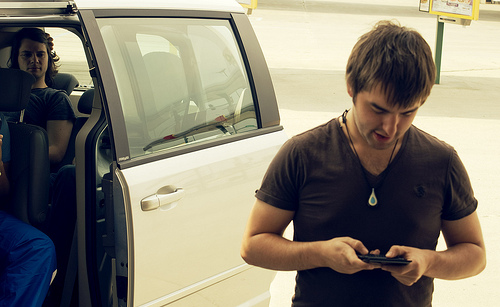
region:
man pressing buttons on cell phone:
[240, 10, 490, 304]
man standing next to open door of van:
[239, 17, 490, 303]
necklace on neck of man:
[334, 98, 411, 213]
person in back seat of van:
[2, 25, 74, 182]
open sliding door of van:
[64, 0, 288, 305]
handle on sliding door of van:
[133, 181, 198, 213]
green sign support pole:
[428, 16, 454, 87]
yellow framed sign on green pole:
[416, 0, 486, 87]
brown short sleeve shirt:
[252, 116, 480, 306]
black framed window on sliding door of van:
[81, 5, 286, 170]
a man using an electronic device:
[240, 18, 485, 305]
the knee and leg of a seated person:
[1, 208, 62, 305]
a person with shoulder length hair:
[5, 27, 78, 180]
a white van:
[0, 1, 282, 304]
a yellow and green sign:
[420, 0, 477, 87]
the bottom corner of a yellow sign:
[238, 1, 258, 13]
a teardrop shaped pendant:
[365, 185, 378, 205]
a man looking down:
[238, 18, 488, 303]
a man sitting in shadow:
[3, 23, 75, 181]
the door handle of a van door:
[140, 178, 185, 215]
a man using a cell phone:
[318, 30, 445, 282]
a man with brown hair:
[326, 13, 453, 103]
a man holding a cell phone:
[333, 238, 430, 282]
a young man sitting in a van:
[2, 18, 69, 149]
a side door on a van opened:
[6, 8, 265, 305]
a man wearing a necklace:
[349, 47, 438, 216]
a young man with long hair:
[12, 25, 64, 86]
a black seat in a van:
[6, 72, 50, 227]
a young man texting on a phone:
[314, 198, 439, 293]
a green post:
[423, 9, 457, 85]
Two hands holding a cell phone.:
[326, 236, 426, 286]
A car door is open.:
[45, 2, 287, 300]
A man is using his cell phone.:
[241, 23, 487, 303]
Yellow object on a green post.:
[418, 0, 480, 86]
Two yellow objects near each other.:
[241, 0, 481, 22]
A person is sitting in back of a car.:
[1, 26, 99, 182]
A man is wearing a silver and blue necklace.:
[337, 106, 399, 206]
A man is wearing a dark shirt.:
[255, 115, 480, 302]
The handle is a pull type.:
[140, 182, 191, 212]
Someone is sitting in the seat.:
[1, 113, 63, 303]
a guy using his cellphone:
[237, 18, 485, 304]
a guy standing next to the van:
[15, 1, 499, 303]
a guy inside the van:
[6, 25, 78, 165]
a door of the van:
[68, 3, 300, 302]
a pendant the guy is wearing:
[366, 187, 378, 205]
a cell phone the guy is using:
[354, 250, 414, 265]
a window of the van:
[80, 9, 273, 161]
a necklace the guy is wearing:
[340, 107, 409, 209]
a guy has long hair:
[7, 28, 62, 85]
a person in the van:
[1, 23, 219, 302]